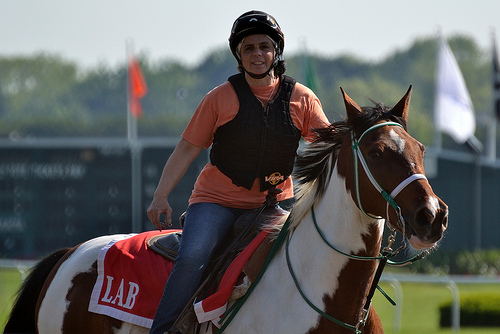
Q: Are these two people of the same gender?
A: No, they are both male and female.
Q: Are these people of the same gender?
A: No, they are both male and female.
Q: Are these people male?
A: No, they are both male and female.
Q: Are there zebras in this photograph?
A: No, there are no zebras.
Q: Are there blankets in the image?
A: Yes, there is a blanket.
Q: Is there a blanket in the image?
A: Yes, there is a blanket.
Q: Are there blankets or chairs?
A: Yes, there is a blanket.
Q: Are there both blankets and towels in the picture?
A: No, there is a blanket but no towels.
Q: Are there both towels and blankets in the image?
A: No, there is a blanket but no towels.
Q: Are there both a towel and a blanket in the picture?
A: No, there is a blanket but no towels.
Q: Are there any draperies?
A: No, there are no draperies.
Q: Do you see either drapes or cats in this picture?
A: No, there are no drapes or cats.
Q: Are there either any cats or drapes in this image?
A: No, there are no drapes or cats.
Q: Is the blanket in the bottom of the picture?
A: Yes, the blanket is in the bottom of the image.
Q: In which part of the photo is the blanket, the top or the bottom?
A: The blanket is in the bottom of the image.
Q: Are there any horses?
A: Yes, there is a horse.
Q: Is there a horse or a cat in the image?
A: Yes, there is a horse.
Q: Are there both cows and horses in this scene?
A: No, there is a horse but no cows.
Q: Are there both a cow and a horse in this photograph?
A: No, there is a horse but no cows.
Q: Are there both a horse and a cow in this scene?
A: No, there is a horse but no cows.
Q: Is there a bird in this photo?
A: No, there are no birds.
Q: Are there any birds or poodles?
A: No, there are no birds or poodles.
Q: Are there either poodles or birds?
A: No, there are no birds or poodles.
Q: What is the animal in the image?
A: The animal is a horse.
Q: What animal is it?
A: The animal is a horse.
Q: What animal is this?
A: That is a horse.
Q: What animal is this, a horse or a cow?
A: That is a horse.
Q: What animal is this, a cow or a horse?
A: That is a horse.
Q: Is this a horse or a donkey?
A: This is a horse.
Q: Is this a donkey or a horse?
A: This is a horse.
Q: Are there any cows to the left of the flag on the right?
A: No, there is a horse to the left of the flag.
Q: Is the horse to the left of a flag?
A: Yes, the horse is to the left of a flag.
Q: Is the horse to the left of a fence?
A: No, the horse is to the left of a flag.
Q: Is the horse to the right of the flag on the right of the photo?
A: No, the horse is to the left of the flag.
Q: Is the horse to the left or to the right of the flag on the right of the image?
A: The horse is to the left of the flag.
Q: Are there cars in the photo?
A: No, there are no cars.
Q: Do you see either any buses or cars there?
A: No, there are no cars or buses.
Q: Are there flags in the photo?
A: Yes, there is a flag.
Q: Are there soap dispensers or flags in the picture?
A: Yes, there is a flag.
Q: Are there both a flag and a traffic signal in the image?
A: No, there is a flag but no traffic lights.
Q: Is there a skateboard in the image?
A: No, there are no skateboards.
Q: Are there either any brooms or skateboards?
A: No, there are no skateboards or brooms.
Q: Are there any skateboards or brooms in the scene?
A: No, there are no skateboards or brooms.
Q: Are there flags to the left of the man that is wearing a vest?
A: Yes, there is a flag to the left of the man.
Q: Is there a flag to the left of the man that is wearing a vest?
A: Yes, there is a flag to the left of the man.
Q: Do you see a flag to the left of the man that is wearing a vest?
A: Yes, there is a flag to the left of the man.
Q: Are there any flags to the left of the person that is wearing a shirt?
A: Yes, there is a flag to the left of the man.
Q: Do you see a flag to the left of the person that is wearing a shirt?
A: Yes, there is a flag to the left of the man.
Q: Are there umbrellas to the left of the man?
A: No, there is a flag to the left of the man.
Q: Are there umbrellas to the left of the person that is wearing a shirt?
A: No, there is a flag to the left of the man.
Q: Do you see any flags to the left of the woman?
A: Yes, there is a flag to the left of the woman.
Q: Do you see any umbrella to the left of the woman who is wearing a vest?
A: No, there is a flag to the left of the woman.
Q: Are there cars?
A: No, there are no cars.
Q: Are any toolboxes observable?
A: No, there are no toolboxes.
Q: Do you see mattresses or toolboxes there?
A: No, there are no toolboxes or mattresses.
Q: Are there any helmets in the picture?
A: Yes, there is a helmet.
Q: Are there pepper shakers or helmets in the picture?
A: Yes, there is a helmet.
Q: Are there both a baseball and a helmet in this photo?
A: No, there is a helmet but no baseballs.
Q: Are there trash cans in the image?
A: No, there are no trash cans.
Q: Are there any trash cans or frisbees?
A: No, there are no trash cans or frisbees.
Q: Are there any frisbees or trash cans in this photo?
A: No, there are no trash cans or frisbees.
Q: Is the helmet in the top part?
A: Yes, the helmet is in the top of the image.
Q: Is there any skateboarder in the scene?
A: No, there are no skateboarders.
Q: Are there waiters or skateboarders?
A: No, there are no skateboarders or waiters.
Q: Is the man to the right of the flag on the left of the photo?
A: Yes, the man is to the right of the flag.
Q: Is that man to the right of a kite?
A: No, the man is to the right of the flag.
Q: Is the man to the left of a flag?
A: No, the man is to the right of a flag.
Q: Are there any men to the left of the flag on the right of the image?
A: Yes, there is a man to the left of the flag.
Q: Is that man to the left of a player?
A: No, the man is to the left of the flag.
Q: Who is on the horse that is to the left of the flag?
A: The man is on the horse.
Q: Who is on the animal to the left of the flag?
A: The man is on the horse.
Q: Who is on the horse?
A: The man is on the horse.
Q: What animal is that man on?
A: The man is on the horse.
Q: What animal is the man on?
A: The man is on the horse.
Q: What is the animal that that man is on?
A: The animal is a horse.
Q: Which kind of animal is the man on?
A: The man is on the horse.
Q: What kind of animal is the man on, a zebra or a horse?
A: The man is on a horse.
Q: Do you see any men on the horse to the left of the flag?
A: Yes, there is a man on the horse.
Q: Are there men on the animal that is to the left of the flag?
A: Yes, there is a man on the horse.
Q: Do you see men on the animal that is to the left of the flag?
A: Yes, there is a man on the horse.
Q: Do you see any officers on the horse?
A: No, there is a man on the horse.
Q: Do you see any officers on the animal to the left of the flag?
A: No, there is a man on the horse.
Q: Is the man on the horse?
A: Yes, the man is on the horse.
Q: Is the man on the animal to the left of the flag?
A: Yes, the man is on the horse.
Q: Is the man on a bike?
A: No, the man is on the horse.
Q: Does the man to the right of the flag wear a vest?
A: Yes, the man wears a vest.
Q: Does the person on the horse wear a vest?
A: Yes, the man wears a vest.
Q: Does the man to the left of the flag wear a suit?
A: No, the man wears a vest.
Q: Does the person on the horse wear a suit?
A: No, the man wears a vest.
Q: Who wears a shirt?
A: The man wears a shirt.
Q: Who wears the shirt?
A: The man wears a shirt.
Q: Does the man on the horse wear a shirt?
A: Yes, the man wears a shirt.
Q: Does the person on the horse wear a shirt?
A: Yes, the man wears a shirt.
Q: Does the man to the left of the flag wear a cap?
A: No, the man wears a shirt.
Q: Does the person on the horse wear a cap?
A: No, the man wears a shirt.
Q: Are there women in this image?
A: Yes, there is a woman.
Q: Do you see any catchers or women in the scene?
A: Yes, there is a woman.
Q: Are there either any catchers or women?
A: Yes, there is a woman.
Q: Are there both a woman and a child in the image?
A: No, there is a woman but no children.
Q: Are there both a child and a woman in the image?
A: No, there is a woman but no children.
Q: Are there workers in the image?
A: No, there are no workers.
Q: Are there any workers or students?
A: No, there are no workers or students.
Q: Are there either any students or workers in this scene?
A: No, there are no workers or students.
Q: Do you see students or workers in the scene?
A: No, there are no workers or students.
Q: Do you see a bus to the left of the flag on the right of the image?
A: No, there is a woman to the left of the flag.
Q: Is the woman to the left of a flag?
A: Yes, the woman is to the left of a flag.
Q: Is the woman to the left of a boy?
A: No, the woman is to the left of a flag.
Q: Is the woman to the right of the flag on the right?
A: No, the woman is to the left of the flag.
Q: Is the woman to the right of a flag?
A: Yes, the woman is to the right of a flag.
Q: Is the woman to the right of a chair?
A: No, the woman is to the right of a flag.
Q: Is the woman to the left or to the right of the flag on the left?
A: The woman is to the right of the flag.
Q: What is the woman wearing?
A: The woman is wearing a vest.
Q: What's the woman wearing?
A: The woman is wearing a vest.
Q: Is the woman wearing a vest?
A: Yes, the woman is wearing a vest.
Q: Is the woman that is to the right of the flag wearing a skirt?
A: No, the woman is wearing a vest.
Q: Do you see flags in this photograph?
A: Yes, there is a flag.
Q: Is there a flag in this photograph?
A: Yes, there is a flag.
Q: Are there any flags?
A: Yes, there is a flag.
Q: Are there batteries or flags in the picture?
A: Yes, there is a flag.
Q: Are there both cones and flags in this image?
A: No, there is a flag but no cones.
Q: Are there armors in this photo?
A: No, there are no armors.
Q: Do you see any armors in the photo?
A: No, there are no armors.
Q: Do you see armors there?
A: No, there are no armors.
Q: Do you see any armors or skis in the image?
A: No, there are no armors or skis.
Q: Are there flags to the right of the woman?
A: Yes, there is a flag to the right of the woman.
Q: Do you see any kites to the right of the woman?
A: No, there is a flag to the right of the woman.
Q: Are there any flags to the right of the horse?
A: Yes, there is a flag to the right of the horse.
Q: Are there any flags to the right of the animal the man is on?
A: Yes, there is a flag to the right of the horse.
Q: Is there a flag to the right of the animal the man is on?
A: Yes, there is a flag to the right of the horse.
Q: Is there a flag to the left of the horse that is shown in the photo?
A: No, the flag is to the right of the horse.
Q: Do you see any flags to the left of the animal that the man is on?
A: No, the flag is to the right of the horse.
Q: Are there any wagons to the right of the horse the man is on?
A: No, there is a flag to the right of the horse.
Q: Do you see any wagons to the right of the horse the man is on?
A: No, there is a flag to the right of the horse.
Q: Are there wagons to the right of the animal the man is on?
A: No, there is a flag to the right of the horse.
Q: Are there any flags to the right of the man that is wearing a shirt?
A: Yes, there is a flag to the right of the man.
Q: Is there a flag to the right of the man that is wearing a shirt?
A: Yes, there is a flag to the right of the man.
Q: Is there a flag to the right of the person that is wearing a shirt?
A: Yes, there is a flag to the right of the man.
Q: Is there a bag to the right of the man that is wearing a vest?
A: No, there is a flag to the right of the man.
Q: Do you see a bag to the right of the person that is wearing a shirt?
A: No, there is a flag to the right of the man.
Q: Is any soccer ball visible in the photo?
A: No, there are no soccer balls.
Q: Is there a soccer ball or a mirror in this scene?
A: No, there are no soccer balls or mirrors.